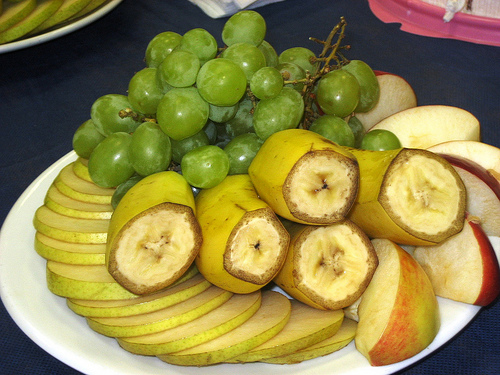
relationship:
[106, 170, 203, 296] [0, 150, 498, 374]
banana on plate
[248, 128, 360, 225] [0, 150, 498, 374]
banana on plate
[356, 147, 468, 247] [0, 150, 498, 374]
banana on plate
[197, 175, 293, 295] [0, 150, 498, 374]
banana on plate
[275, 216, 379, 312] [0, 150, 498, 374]
banana on plate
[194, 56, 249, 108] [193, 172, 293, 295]
grape on top of banana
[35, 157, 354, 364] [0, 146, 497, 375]
fruit on plate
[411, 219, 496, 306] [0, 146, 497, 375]
apple on plate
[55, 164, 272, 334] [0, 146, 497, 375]
apples on plate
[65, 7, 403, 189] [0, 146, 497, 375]
grapes on plate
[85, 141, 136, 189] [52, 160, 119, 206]
grape next to apples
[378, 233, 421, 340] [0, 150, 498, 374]
slice on plate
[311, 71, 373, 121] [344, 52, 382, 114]
grape next to grape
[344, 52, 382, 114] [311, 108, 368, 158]
grape next to grape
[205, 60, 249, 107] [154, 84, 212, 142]
grape next to grapes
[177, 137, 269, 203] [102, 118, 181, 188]
grape next to grape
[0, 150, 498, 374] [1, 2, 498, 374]
plate on table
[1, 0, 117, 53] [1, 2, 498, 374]
plate on table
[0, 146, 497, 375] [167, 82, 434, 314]
plate full of fruit